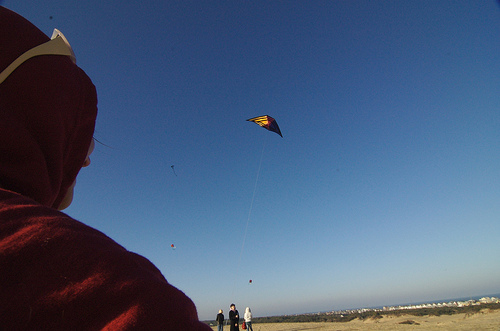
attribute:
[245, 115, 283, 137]
kite — yellow, flying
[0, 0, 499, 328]
sky — blue, clear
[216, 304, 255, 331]
people — looking, standing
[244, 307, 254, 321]
jacket — white, dark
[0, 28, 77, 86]
sunglasses — white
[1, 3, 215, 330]
hoodie — red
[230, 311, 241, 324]
shirt — black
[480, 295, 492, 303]
building — white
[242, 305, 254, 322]
coat — white